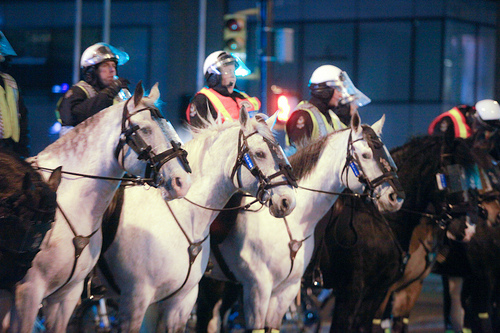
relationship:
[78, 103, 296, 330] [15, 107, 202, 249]
horse to left of horse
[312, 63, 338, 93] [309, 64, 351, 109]
helmet on head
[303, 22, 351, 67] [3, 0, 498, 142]
window of building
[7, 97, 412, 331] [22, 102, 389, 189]
three horses with different manes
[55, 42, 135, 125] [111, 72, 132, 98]
officer drinking from a water bottle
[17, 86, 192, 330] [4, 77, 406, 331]
horses in a row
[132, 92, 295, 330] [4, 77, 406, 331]
horses in a row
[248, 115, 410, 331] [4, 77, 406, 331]
horses in a row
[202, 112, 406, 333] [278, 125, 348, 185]
horse with brown mane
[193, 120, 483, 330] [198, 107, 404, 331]
horse to right of horse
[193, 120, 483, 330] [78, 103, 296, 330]
horse to right of horse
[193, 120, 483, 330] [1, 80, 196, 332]
horse to right of horse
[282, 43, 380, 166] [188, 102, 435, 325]
officer on a horse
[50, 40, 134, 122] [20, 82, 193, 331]
officer on horse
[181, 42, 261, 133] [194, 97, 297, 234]
officer on horse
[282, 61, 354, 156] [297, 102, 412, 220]
officer on horse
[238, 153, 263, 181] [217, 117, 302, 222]
bridle on horse face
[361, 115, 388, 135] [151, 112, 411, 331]
ear on horse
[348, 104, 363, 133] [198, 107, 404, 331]
ear on horse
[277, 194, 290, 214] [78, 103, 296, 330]
nose on horse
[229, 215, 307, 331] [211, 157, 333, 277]
chest on horse